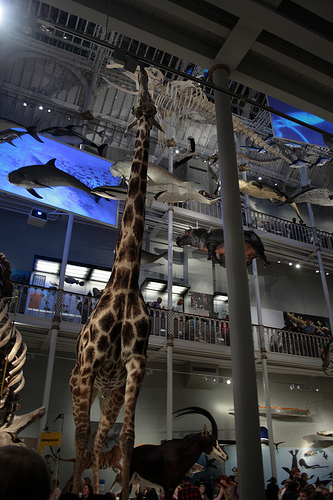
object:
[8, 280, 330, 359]
railing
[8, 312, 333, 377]
walkway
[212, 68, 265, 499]
pillar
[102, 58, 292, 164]
bones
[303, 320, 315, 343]
person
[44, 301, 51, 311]
person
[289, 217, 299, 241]
person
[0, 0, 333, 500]
museum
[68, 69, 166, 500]
giraffe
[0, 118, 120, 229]
aquarium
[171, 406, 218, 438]
horns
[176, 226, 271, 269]
hippo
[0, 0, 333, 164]
ceiling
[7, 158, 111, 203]
animal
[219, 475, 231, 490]
hair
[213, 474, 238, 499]
woman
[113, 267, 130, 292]
brown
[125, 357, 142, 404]
white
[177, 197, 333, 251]
railing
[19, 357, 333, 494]
white wall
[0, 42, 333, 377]
balconies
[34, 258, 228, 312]
lights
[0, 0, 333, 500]
display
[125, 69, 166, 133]
head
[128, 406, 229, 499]
animal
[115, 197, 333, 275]
walkway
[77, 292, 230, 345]
people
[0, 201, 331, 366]
second floor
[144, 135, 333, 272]
third floor